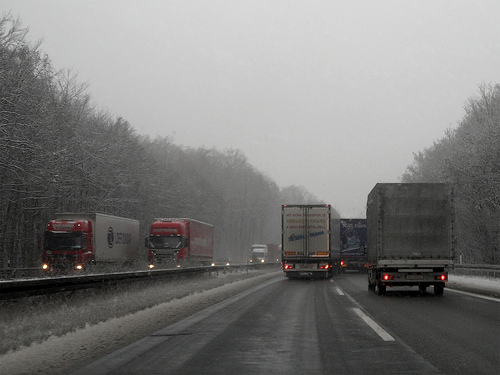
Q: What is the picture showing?
A: Trucks driving on the road.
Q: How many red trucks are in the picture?
A: Two.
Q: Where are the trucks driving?
A: On the road.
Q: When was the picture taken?
A: During the day.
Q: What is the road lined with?
A: Trees.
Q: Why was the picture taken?
A: To capture the trucks driving.